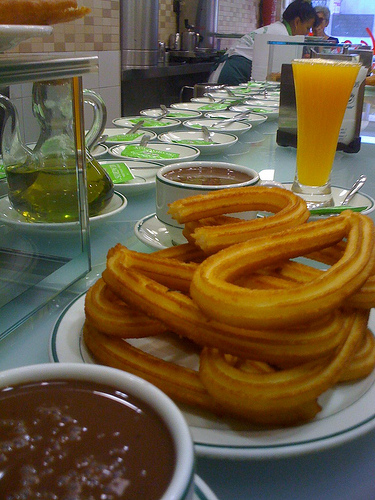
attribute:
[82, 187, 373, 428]
churros — stacked, ridged, fried, crispy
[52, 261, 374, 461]
plate — white, green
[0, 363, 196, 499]
bowl — white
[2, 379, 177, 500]
sauce — brown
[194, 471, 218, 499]
saucer — white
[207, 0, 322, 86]
woman — serving, working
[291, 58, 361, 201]
glass — filled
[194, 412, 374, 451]
trim — green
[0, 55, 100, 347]
case — glass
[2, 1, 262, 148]
wall — tiled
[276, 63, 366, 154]
napkin holder — stainless steel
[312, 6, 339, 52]
lady — waiting